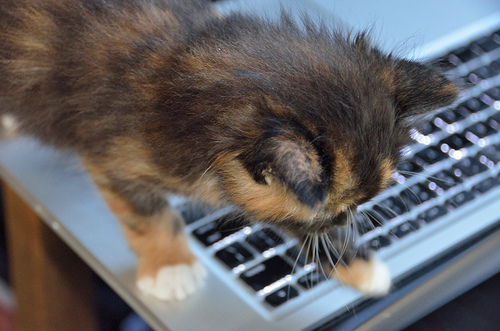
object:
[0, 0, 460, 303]
cat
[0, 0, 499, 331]
keyboard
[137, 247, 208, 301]
paw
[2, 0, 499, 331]
laptop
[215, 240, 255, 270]
key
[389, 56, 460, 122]
ear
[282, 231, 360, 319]
whiskers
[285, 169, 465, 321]
eyelash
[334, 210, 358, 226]
nose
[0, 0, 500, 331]
desk